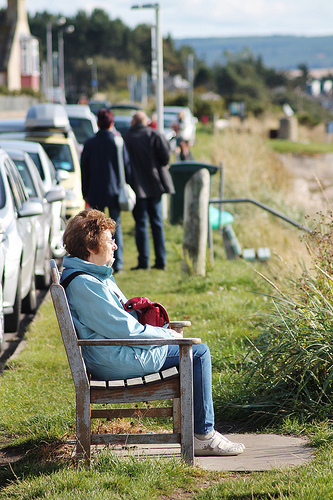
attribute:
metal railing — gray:
[205, 192, 330, 285]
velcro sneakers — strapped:
[192, 428, 245, 457]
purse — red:
[127, 281, 173, 330]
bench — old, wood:
[43, 254, 203, 465]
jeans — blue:
[162, 341, 212, 434]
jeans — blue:
[109, 196, 182, 271]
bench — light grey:
[25, 259, 219, 444]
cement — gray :
[107, 422, 315, 470]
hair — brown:
[52, 205, 112, 256]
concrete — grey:
[94, 431, 319, 478]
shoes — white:
[174, 416, 262, 455]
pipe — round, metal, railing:
[210, 198, 312, 233]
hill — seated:
[1, 121, 329, 498]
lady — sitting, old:
[59, 207, 246, 457]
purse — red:
[123, 284, 179, 338]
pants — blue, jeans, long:
[151, 333, 216, 432]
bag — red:
[89, 270, 197, 338]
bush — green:
[231, 269, 326, 421]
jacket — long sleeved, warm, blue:
[60, 251, 168, 378]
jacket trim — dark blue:
[61, 265, 99, 288]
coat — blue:
[60, 255, 171, 379]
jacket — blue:
[58, 253, 179, 380]